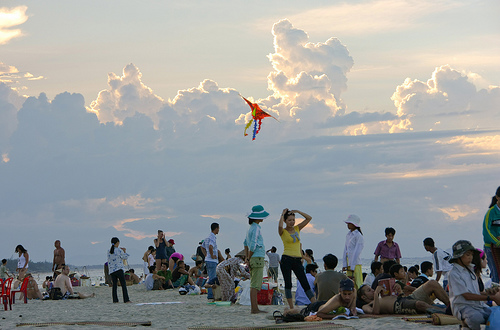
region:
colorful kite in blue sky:
[234, 84, 275, 176]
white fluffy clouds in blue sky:
[281, 25, 357, 67]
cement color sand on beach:
[161, 308, 202, 323]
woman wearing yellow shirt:
[273, 203, 313, 273]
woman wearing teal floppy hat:
[240, 199, 278, 242]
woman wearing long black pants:
[95, 267, 145, 302]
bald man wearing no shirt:
[47, 212, 76, 284]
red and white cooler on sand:
[253, 270, 290, 312]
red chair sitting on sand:
[12, 268, 34, 300]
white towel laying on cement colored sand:
[138, 291, 198, 328]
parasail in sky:
[215, 75, 289, 165]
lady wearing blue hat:
[227, 185, 271, 328]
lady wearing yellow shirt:
[272, 195, 318, 322]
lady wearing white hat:
[333, 201, 383, 322]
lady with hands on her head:
[274, 190, 326, 323]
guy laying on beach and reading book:
[354, 267, 466, 328]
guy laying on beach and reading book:
[252, 272, 377, 328]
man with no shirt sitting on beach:
[42, 256, 97, 311]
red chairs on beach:
[0, 263, 37, 310]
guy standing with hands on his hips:
[183, 214, 229, 316]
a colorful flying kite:
[228, 95, 282, 146]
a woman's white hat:
[344, 211, 364, 228]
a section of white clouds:
[269, 19, 356, 74]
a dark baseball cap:
[338, 276, 355, 291]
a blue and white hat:
[246, 200, 270, 220]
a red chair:
[7, 272, 32, 305]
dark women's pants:
[108, 267, 130, 302]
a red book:
[375, 277, 400, 297]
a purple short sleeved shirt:
[371, 241, 403, 260]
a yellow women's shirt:
[279, 225, 309, 257]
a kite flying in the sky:
[239, 92, 276, 145]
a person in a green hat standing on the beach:
[247, 205, 268, 315]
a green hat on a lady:
[246, 202, 270, 222]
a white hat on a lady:
[345, 214, 363, 231]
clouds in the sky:
[268, 19, 355, 120]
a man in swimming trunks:
[52, 236, 65, 271]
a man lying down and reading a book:
[358, 276, 451, 320]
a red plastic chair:
[11, 277, 31, 304]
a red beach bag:
[253, 282, 275, 308]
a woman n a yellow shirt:
[277, 209, 318, 306]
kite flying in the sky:
[228, 84, 280, 145]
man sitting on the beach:
[45, 255, 89, 308]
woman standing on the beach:
[100, 230, 143, 303]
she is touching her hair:
[268, 201, 328, 316]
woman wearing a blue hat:
[227, 194, 283, 320]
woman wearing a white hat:
[333, 201, 371, 312]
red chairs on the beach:
[0, 268, 43, 314]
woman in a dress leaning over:
[207, 244, 247, 309]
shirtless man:
[40, 230, 80, 280]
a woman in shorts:
[145, 225, 177, 292]